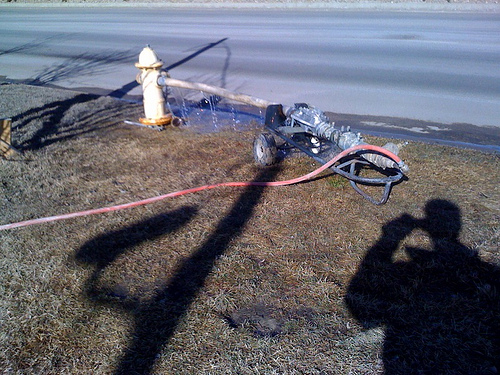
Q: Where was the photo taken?
A: It was taken at the pavement.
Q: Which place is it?
A: It is a pavement.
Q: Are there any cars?
A: No, there are no cars.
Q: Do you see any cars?
A: No, there are no cars.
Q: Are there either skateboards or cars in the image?
A: No, there are no cars or skateboards.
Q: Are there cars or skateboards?
A: No, there are no cars or skateboards.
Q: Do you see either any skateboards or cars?
A: No, there are no cars or skateboards.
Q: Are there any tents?
A: No, there are no tents.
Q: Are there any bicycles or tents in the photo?
A: No, there are no tents or bicycles.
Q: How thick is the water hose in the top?
A: The hose is thick.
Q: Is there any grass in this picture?
A: Yes, there is grass.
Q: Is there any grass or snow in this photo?
A: Yes, there is grass.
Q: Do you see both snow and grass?
A: No, there is grass but no snow.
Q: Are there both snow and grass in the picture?
A: No, there is grass but no snow.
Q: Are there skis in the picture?
A: No, there are no skis.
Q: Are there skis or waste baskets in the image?
A: No, there are no skis or waste baskets.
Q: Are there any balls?
A: No, there are no balls.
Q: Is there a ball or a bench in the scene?
A: No, there are no balls or benches.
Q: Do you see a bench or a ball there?
A: No, there are no balls or benches.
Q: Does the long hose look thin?
A: Yes, the water hose is thin.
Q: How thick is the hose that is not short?
A: The water hose is thin.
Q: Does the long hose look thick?
A: No, the water hose is thin.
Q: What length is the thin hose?
A: The hose is long.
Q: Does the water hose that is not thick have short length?
A: No, the water hose is long.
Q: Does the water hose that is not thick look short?
A: No, the water hose is long.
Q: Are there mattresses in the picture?
A: No, there are no mattresses.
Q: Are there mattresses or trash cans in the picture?
A: No, there are no mattresses or trash cans.